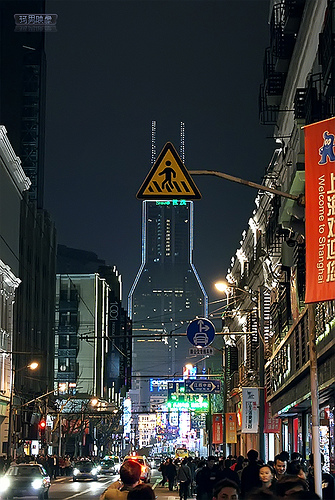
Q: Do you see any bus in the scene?
A: No, there are no buses.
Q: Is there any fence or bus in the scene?
A: No, there are no buses or fences.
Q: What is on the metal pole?
A: The sign is on the pole.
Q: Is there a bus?
A: No, there are no buses.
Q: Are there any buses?
A: No, there are no buses.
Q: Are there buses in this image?
A: No, there are no buses.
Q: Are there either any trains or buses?
A: No, there are no buses or trains.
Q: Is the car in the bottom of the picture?
A: Yes, the car is in the bottom of the image.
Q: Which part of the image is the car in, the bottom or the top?
A: The car is in the bottom of the image.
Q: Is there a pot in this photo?
A: No, there are no pots.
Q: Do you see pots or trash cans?
A: No, there are no pots or trash cans.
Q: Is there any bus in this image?
A: No, there are no buses.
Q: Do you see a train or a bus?
A: No, there are no buses or trains.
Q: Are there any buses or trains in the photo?
A: No, there are no buses or trains.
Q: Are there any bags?
A: No, there are no bags.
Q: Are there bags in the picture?
A: No, there are no bags.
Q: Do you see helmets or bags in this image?
A: No, there are no bags or helmets.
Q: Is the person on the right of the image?
A: Yes, the person is on the right of the image.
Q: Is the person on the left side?
A: No, the person is on the right of the image.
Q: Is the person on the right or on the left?
A: The person is on the right of the image.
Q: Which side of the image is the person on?
A: The person is on the right of the image.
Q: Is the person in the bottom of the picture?
A: Yes, the person is in the bottom of the image.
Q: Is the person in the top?
A: No, the person is in the bottom of the image.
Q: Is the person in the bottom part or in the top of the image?
A: The person is in the bottom of the image.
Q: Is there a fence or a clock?
A: No, there are no fences or clocks.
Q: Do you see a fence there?
A: No, there are no fences.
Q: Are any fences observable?
A: No, there are no fences.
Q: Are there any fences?
A: No, there are no fences.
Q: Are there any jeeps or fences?
A: No, there are no fences or jeeps.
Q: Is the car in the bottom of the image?
A: Yes, the car is in the bottom of the image.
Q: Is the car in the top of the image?
A: No, the car is in the bottom of the image.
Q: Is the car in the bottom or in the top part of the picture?
A: The car is in the bottom of the image.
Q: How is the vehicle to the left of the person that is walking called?
A: The vehicle is a car.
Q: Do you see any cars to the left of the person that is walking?
A: Yes, there is a car to the left of the person.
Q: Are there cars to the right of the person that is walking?
A: No, the car is to the left of the person.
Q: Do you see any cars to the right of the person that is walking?
A: No, the car is to the left of the person.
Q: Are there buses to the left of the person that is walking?
A: No, there is a car to the left of the person.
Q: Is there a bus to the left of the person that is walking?
A: No, there is a car to the left of the person.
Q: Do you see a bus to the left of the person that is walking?
A: No, there is a car to the left of the person.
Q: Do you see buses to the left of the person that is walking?
A: No, there is a car to the left of the person.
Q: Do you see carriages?
A: No, there are no carriages.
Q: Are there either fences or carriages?
A: No, there are no carriages or fences.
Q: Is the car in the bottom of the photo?
A: Yes, the car is in the bottom of the image.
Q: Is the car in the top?
A: No, the car is in the bottom of the image.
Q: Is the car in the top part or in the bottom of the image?
A: The car is in the bottom of the image.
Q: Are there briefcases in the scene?
A: No, there are no briefcases.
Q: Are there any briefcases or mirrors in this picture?
A: No, there are no briefcases or mirrors.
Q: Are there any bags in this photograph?
A: No, there are no bags.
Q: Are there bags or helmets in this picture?
A: No, there are no bags or helmets.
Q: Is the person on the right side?
A: Yes, the person is on the right of the image.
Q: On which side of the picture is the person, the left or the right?
A: The person is on the right of the image.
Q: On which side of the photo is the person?
A: The person is on the right of the image.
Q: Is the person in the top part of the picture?
A: No, the person is in the bottom of the image.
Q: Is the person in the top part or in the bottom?
A: The person is in the bottom of the image.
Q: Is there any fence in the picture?
A: No, there are no fences.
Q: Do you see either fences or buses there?
A: No, there are no fences or buses.